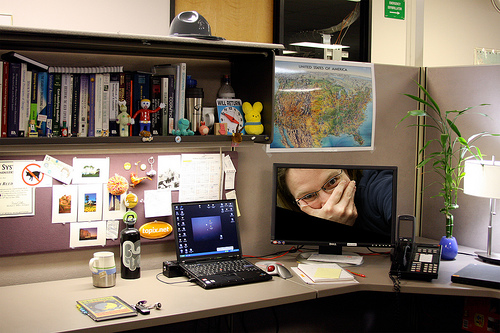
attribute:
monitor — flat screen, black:
[271, 163, 397, 248]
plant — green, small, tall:
[395, 77, 500, 236]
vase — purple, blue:
[438, 237, 458, 261]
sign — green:
[385, 1, 404, 20]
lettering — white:
[388, 2, 402, 10]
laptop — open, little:
[171, 199, 271, 287]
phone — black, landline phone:
[390, 238, 442, 321]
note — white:
[419, 252, 435, 263]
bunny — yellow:
[242, 102, 264, 134]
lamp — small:
[463, 156, 499, 263]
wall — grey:
[237, 61, 420, 257]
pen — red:
[346, 267, 364, 277]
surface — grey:
[0, 235, 500, 333]